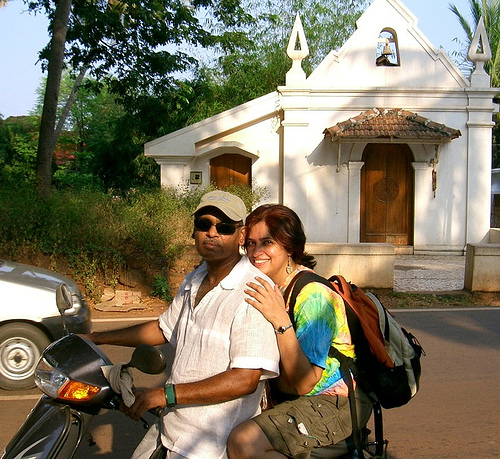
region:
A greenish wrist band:
[164, 382, 177, 405]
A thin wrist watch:
[276, 319, 293, 334]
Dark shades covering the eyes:
[195, 219, 235, 235]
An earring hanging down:
[283, 253, 293, 277]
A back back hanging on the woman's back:
[332, 275, 424, 407]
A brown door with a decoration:
[361, 143, 412, 242]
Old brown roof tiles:
[375, 116, 410, 132]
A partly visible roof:
[57, 144, 77, 162]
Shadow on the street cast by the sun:
[413, 311, 495, 327]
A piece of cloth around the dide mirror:
[100, 363, 139, 407]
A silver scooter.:
[3, 278, 196, 458]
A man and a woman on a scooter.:
[7, 187, 429, 458]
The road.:
[0, 309, 497, 457]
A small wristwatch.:
[270, 324, 296, 334]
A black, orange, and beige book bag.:
[284, 265, 431, 412]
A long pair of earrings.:
[279, 249, 294, 274]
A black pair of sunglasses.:
[191, 218, 245, 236]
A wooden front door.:
[362, 139, 417, 242]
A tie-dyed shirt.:
[276, 262, 357, 397]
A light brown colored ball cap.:
[190, 186, 247, 223]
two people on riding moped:
[34, 183, 422, 445]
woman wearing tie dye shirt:
[224, 199, 399, 447]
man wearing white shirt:
[112, 186, 274, 456]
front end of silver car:
[2, 255, 102, 386]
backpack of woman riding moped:
[280, 270, 425, 401]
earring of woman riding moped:
[280, 247, 293, 277]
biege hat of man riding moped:
[184, 186, 250, 221]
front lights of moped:
[28, 353, 100, 401]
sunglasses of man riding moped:
[193, 218, 243, 239]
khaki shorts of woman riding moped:
[249, 383, 377, 449]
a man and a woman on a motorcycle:
[6, 185, 375, 457]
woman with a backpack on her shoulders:
[282, 269, 425, 412]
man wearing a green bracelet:
[163, 380, 178, 407]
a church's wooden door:
[361, 140, 411, 245]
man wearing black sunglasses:
[193, 218, 241, 235]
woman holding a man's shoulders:
[241, 188, 353, 420]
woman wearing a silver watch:
[270, 320, 297, 332]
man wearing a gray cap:
[192, 188, 247, 222]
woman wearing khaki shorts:
[256, 388, 376, 457]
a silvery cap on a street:
[0, 255, 91, 390]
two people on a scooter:
[0, 188, 425, 456]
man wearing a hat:
[69, 187, 279, 456]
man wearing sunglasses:
[60, 183, 281, 454]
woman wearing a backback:
[222, 200, 422, 450]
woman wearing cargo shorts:
[220, 195, 425, 451]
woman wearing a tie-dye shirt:
[220, 195, 430, 451]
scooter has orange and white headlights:
[2, 280, 170, 457]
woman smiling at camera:
[226, 201, 438, 457]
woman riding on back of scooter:
[225, 200, 432, 457]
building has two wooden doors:
[186, 127, 426, 249]